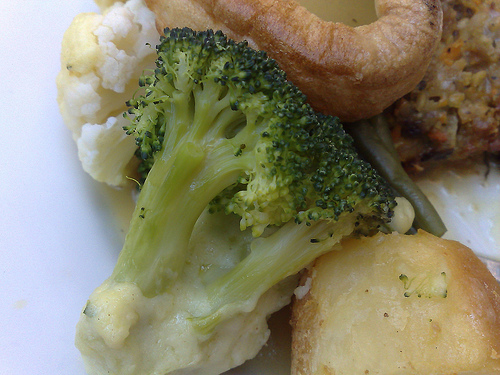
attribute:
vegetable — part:
[73, 22, 400, 373]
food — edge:
[174, 81, 404, 294]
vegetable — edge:
[166, 45, 398, 322]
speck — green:
[63, 61, 75, 74]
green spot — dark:
[137, 207, 145, 220]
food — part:
[282, 232, 494, 374]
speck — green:
[397, 269, 413, 297]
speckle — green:
[157, 29, 395, 220]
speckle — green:
[331, 137, 343, 167]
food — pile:
[40, 0, 493, 373]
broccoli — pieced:
[36, 55, 386, 312]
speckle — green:
[322, 179, 335, 193]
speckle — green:
[352, 172, 364, 184]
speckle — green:
[288, 160, 306, 174]